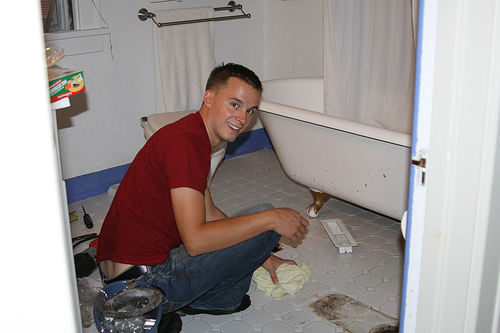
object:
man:
[94, 61, 308, 333]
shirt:
[96, 111, 212, 265]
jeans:
[97, 202, 283, 317]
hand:
[260, 254, 298, 285]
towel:
[250, 262, 311, 300]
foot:
[305, 186, 331, 219]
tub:
[257, 76, 412, 221]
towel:
[152, 6, 215, 114]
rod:
[136, 0, 252, 27]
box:
[43, 68, 85, 104]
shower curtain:
[322, 0, 418, 135]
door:
[399, 0, 500, 331]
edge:
[396, 0, 430, 333]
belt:
[99, 264, 149, 287]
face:
[209, 75, 261, 143]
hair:
[200, 61, 263, 107]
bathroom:
[38, 2, 429, 333]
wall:
[37, 0, 325, 205]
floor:
[66, 147, 402, 333]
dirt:
[308, 291, 399, 332]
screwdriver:
[81, 205, 94, 229]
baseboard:
[62, 127, 273, 205]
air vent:
[319, 218, 358, 254]